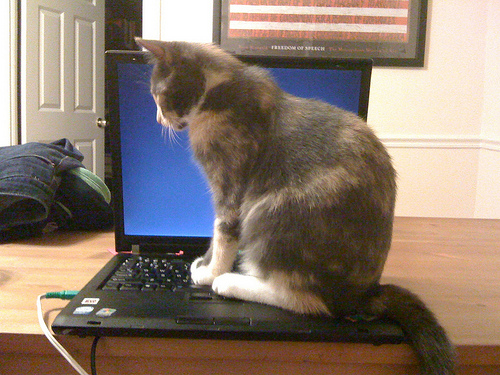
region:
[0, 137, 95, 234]
dark blue jeans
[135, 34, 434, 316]
brown and orange cat with white paws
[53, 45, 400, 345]
black laptop computer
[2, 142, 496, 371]
light colored wooden table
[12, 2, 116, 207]
white wooden door with silver knob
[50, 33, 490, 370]
housecat sitting on a laptop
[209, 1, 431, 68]
the bottom of an American Flag poster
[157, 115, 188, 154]
cat's whiskers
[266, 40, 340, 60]
the caption "Freedom of Speech"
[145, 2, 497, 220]
white painted walls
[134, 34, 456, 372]
multicolored adult cat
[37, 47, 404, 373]
connected black laptop computer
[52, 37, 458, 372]
cat sitting on laptop keyboard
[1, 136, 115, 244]
clothing laying on wooden desk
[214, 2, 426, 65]
framed picture of American flag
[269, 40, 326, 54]
words saying "Freedom of Speech"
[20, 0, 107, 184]
open white closet door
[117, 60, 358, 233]
plain blue desktop screen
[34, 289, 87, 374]
green and white cord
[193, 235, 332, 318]
cat's white front and back feet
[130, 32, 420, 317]
Cat on a computer.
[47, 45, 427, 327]
Small black laptop.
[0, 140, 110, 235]
Crumpled blue jeans.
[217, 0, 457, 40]
Picture of USA flag.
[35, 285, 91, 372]
Computer wire.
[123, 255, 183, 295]
Keyboard on the laptop.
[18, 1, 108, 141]
Door out of the room.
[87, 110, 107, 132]
Small shiny doorknob.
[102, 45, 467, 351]
Laptop with a cat on top of it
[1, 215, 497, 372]
Wood table with computer on top.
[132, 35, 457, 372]
A cat sitting on a laptop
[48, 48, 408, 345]
A laptop is on a table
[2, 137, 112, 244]
some clothes are on the table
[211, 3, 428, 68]
The bottom part of a picture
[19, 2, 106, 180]
a door is open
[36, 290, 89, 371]
a cord is plugged into a laptop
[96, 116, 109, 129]
a doorknob on the door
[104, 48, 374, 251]
a blue screen on the laptop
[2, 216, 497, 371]
a wood table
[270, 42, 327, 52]
words are on a picture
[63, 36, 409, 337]
Gray and white cat sitting on the laptop keyboard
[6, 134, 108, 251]
Pile of blue jeans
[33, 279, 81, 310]
Green and white cord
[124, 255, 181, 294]
Black keys with white letters on the keyboard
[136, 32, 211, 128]
Cats pointy ear and little pink nose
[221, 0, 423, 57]
Red and white stripe poster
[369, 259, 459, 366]
The cats gray tail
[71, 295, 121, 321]
Sticker on the black laptop computer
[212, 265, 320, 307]
White cat paw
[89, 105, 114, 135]
Silver door knob